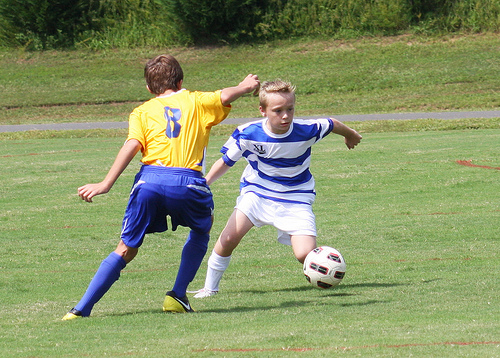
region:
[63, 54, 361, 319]
two children are playing soccer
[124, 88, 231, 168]
yellow shirt with a blue number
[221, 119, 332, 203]
blue and white striped shirt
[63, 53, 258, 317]
boy trying to get the ball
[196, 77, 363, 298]
young child kicking a ball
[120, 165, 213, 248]
blue shorts with white on them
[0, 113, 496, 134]
concrete walking path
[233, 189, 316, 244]
white sports shorts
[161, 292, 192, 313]
black cleats with a white strip and yellow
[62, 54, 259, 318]
little boy with brown hair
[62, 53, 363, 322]
Two kids playing soccer on a field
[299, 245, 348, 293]
Soccer ball in the air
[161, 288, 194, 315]
Yellow and black Nike cleat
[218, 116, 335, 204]
Blue and white t-shirt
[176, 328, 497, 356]
Red stripe on grass field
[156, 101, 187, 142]
Number 8 on back of jersey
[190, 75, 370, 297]
Boy dribbling soccer ball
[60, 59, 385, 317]
Boy defending opposing player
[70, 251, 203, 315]
Blue knee length tube socks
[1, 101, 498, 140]
Paved path bordering playing field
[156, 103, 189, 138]
Number 8 on boys shirt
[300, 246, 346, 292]
White soccer ball on ground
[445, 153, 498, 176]
Red marking in the grass far right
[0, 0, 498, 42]
A bunch of trees together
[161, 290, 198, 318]
Right yellow soccer shoe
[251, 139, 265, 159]
Size on shirt that says XL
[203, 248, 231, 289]
White soccer sock on left knee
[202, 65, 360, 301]
Boy trying to get the ball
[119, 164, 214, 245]
Blue soccer shorts on the boy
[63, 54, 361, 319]
Two boys playing soccer against each other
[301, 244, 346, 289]
A soccer ball on the field that is mostly white.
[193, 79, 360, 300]
A blonde boy in white shorts and a blue and white shirt.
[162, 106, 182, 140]
A blue number 8 on the back of a boy.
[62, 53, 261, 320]
The back of a brown haired boy in a yellow jersey.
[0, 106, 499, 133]
A grey walkway past the grass.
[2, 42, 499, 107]
Greener grass past the grey path.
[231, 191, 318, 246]
White shorts on a boy.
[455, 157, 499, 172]
A red stripe on the ground.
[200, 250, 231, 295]
A high white sock on a blonde boy.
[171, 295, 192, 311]
White Nike swoosh on a boy's right cleat.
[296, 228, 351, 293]
soccer ball on the field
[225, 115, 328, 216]
boy wearing a white and blue shirt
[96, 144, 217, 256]
boy wearing blue shorts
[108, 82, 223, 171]
boy wearing yellow shirt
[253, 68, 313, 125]
boy with blond hair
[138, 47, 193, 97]
boy with brown hair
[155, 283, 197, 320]
boy wearing sneakers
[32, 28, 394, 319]
two boys playing soccer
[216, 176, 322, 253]
boy wearing white shorts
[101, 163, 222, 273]
boy wearing blue shorts